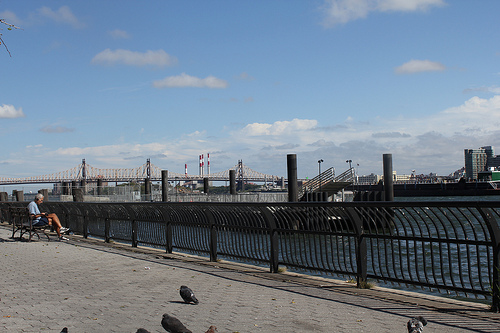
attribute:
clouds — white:
[103, 53, 218, 111]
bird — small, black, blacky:
[155, 277, 222, 301]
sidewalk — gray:
[44, 259, 72, 289]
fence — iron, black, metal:
[360, 202, 432, 259]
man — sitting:
[24, 191, 63, 241]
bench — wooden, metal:
[9, 197, 28, 240]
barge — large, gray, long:
[109, 181, 341, 236]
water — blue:
[416, 190, 488, 218]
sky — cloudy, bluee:
[207, 41, 241, 73]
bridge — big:
[11, 178, 63, 189]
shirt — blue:
[23, 194, 37, 216]